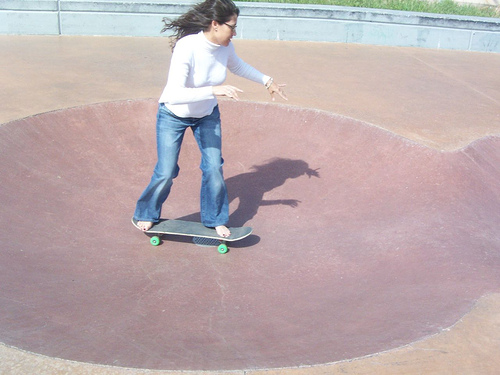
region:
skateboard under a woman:
[133, 206, 257, 261]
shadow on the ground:
[228, 129, 328, 236]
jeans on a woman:
[139, 105, 232, 230]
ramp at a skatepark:
[290, 100, 476, 357]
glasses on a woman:
[223, 20, 237, 34]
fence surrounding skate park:
[345, 6, 476, 60]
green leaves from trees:
[417, 2, 487, 19]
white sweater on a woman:
[147, 35, 272, 123]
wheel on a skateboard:
[213, 237, 233, 261]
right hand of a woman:
[216, 82, 241, 102]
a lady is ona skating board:
[140, 32, 277, 272]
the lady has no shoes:
[144, 186, 261, 268]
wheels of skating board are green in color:
[141, 232, 225, 263]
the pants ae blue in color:
[151, 112, 227, 232]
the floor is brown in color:
[333, 158, 415, 295]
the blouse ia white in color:
[175, 44, 238, 118]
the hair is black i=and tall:
[157, 4, 274, 40]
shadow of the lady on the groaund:
[217, 115, 328, 195]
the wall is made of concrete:
[390, 11, 464, 51]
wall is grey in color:
[362, 13, 437, 54]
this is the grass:
[450, 3, 492, 13]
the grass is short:
[445, 0, 462, 11]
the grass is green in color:
[420, 0, 440, 5]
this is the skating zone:
[285, 277, 354, 339]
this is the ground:
[128, 261, 225, 344]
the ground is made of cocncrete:
[152, 272, 218, 330]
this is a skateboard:
[132, 204, 259, 259]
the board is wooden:
[167, 219, 186, 232]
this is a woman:
[134, 3, 294, 217]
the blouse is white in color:
[183, 66, 213, 76]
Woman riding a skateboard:
[130, 0, 290, 257]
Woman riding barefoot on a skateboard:
[130, 0, 291, 255]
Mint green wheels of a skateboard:
[147, 234, 229, 254]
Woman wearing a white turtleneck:
[130, 0, 289, 240]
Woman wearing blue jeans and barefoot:
[135, 0, 288, 237]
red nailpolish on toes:
[137, 223, 147, 233]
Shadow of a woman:
[167, 152, 324, 235]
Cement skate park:
[0, 0, 498, 371]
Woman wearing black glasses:
[135, 0, 288, 240]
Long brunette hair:
[157, 0, 240, 52]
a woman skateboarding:
[126, 5, 262, 255]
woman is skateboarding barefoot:
[123, 208, 254, 251]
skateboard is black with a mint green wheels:
[125, 210, 261, 255]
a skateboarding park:
[0, 41, 486, 361]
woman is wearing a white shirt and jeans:
[130, 0, 290, 230]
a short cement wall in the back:
[8, 0, 493, 52]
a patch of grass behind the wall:
[251, 0, 494, 15]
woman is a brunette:
[160, 0, 236, 45]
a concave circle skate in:
[0, 81, 485, 371]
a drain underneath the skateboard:
[186, 232, 221, 251]